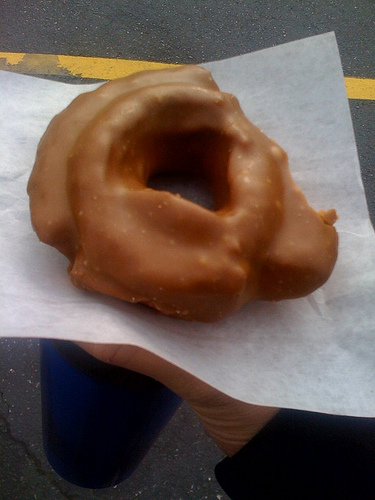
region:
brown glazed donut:
[23, 53, 346, 336]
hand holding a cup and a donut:
[29, 65, 372, 491]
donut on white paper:
[12, 39, 373, 400]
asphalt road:
[4, 4, 365, 57]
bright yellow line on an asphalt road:
[7, 12, 373, 102]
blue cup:
[24, 326, 191, 483]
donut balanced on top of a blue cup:
[15, 56, 315, 493]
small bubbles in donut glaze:
[210, 100, 298, 261]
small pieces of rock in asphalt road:
[1, 0, 374, 71]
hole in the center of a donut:
[84, 74, 280, 239]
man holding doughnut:
[27, 63, 327, 486]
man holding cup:
[21, 307, 218, 482]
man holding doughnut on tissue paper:
[28, 22, 365, 384]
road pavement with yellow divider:
[3, 6, 373, 102]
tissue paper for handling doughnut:
[14, 184, 332, 440]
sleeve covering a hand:
[156, 343, 365, 494]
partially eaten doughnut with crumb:
[73, 29, 364, 297]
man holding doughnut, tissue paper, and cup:
[23, 39, 303, 469]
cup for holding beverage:
[26, 310, 196, 487]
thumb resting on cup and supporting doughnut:
[55, 305, 236, 476]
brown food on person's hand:
[50, 67, 335, 318]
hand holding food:
[110, 348, 267, 446]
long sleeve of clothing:
[215, 420, 361, 482]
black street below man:
[165, 437, 205, 493]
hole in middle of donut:
[141, 113, 255, 214]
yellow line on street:
[36, 33, 122, 90]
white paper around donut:
[261, 49, 330, 110]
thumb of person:
[80, 338, 190, 402]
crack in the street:
[0, 402, 39, 456]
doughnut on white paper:
[18, 35, 324, 323]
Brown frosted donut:
[26, 60, 337, 317]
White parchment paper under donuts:
[197, 27, 363, 196]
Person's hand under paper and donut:
[73, 330, 374, 495]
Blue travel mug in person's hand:
[33, 339, 185, 493]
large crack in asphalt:
[4, 411, 80, 498]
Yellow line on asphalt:
[56, 35, 135, 84]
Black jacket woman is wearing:
[189, 396, 372, 496]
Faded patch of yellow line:
[0, 53, 91, 79]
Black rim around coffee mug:
[32, 323, 180, 410]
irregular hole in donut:
[130, 120, 252, 211]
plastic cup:
[38, 334, 182, 496]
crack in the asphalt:
[0, 391, 90, 499]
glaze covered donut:
[29, 59, 342, 313]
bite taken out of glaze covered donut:
[207, 68, 342, 231]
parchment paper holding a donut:
[0, 23, 372, 417]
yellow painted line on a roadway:
[0, 43, 374, 108]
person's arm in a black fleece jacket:
[160, 355, 374, 498]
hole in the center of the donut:
[128, 120, 245, 223]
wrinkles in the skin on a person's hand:
[171, 384, 281, 475]